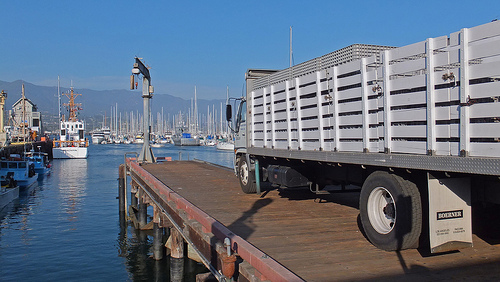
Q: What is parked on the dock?
A: Truck.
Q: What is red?
A: Edge of the dock.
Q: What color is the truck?
A: Gray.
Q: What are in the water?
A: Boats.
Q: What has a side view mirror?
A: Truck.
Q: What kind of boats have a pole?
A: Sail boats.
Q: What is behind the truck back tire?
A: Mud flap.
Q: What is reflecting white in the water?
A: Boats.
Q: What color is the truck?
A: Grey.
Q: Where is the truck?
A: Pier.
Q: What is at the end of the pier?
A: Crane.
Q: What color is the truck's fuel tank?
A: Black.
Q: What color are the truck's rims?
A: White.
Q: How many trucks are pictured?
A: One.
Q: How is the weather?
A: Clear.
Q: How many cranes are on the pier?
A: One.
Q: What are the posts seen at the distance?
A: Masts.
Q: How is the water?
A: Calm.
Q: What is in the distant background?
A: Mountains.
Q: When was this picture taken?
A: Daytime.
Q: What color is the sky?
A: Blue.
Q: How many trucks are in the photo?
A: One.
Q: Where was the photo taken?
A: At the docks.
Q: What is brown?
A: The pier.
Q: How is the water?
A: Calm.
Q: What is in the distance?
A: Mountains.